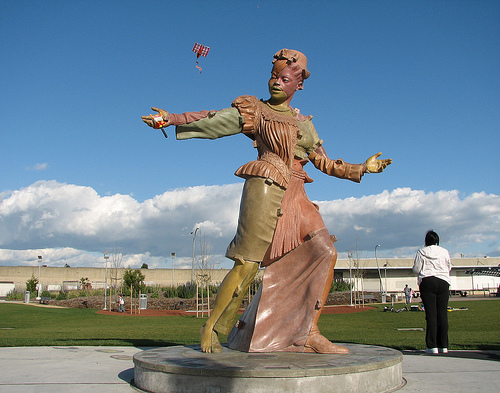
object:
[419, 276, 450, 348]
pants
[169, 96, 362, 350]
dress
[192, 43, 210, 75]
kite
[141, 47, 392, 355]
statue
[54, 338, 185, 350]
shadow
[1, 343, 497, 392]
ground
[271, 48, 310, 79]
hat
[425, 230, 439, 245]
hair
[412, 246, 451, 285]
shirt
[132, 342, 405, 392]
concrete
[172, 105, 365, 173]
arms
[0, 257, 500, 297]
building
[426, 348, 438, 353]
shoe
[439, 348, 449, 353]
shoe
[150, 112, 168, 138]
object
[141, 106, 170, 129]
hand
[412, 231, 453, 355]
person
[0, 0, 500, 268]
sky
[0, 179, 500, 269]
cloud